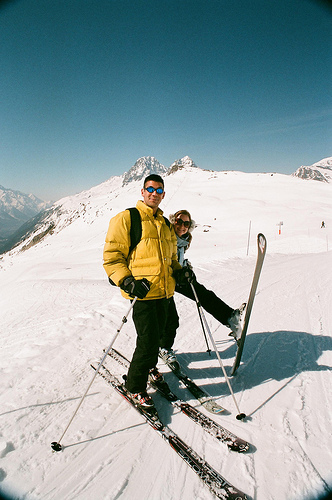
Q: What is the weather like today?
A: It is clear.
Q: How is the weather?
A: It is clear.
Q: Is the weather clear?
A: Yes, it is clear.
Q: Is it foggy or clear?
A: It is clear.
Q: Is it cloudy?
A: No, it is clear.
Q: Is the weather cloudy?
A: No, it is clear.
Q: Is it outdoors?
A: Yes, it is outdoors.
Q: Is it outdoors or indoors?
A: It is outdoors.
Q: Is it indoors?
A: No, it is outdoors.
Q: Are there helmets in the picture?
A: No, there are no helmets.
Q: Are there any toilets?
A: No, there are no toilets.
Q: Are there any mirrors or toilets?
A: No, there are no toilets or mirrors.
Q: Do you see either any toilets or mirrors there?
A: No, there are no toilets or mirrors.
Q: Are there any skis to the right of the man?
A: Yes, there is a ski to the right of the man.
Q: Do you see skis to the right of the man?
A: Yes, there is a ski to the right of the man.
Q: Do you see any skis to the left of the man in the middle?
A: No, the ski is to the right of the man.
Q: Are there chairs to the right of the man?
A: No, there is a ski to the right of the man.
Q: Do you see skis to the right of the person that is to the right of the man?
A: Yes, there is a ski to the right of the person.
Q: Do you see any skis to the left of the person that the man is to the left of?
A: No, the ski is to the right of the person.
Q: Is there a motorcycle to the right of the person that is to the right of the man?
A: No, there is a ski to the right of the person.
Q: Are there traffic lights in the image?
A: No, there are no traffic lights.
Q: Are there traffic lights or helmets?
A: No, there are no traffic lights or helmets.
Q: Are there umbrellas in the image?
A: No, there are no umbrellas.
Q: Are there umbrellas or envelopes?
A: No, there are no umbrellas or envelopes.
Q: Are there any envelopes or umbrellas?
A: No, there are no umbrellas or envelopes.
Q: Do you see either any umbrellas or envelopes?
A: No, there are no umbrellas or envelopes.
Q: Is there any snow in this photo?
A: Yes, there is snow.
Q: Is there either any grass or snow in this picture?
A: Yes, there is snow.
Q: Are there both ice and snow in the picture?
A: No, there is snow but no ice.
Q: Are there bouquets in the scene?
A: No, there are no bouquets.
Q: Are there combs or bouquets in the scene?
A: No, there are no bouquets or combs.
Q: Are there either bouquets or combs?
A: No, there are no bouquets or combs.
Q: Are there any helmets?
A: No, there are no helmets.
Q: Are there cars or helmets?
A: No, there are no helmets or cars.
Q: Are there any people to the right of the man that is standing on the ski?
A: Yes, there is a person to the right of the man.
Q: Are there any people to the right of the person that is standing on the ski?
A: Yes, there is a person to the right of the man.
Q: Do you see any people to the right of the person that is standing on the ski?
A: Yes, there is a person to the right of the man.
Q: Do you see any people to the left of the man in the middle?
A: No, the person is to the right of the man.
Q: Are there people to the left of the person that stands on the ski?
A: No, the person is to the right of the man.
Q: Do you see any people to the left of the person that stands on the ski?
A: No, the person is to the right of the man.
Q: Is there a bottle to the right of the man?
A: No, there is a person to the right of the man.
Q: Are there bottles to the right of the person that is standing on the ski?
A: No, there is a person to the right of the man.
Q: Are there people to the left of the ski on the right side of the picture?
A: Yes, there is a person to the left of the ski.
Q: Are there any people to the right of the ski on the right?
A: No, the person is to the left of the ski.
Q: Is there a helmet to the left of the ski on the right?
A: No, there is a person to the left of the ski.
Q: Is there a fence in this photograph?
A: No, there are no fences.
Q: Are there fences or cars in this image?
A: No, there are no fences or cars.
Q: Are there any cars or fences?
A: No, there are no fences or cars.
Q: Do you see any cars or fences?
A: No, there are no fences or cars.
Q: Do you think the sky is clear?
A: Yes, the sky is clear.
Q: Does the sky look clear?
A: Yes, the sky is clear.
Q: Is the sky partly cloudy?
A: No, the sky is clear.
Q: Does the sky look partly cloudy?
A: No, the sky is clear.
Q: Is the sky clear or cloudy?
A: The sky is clear.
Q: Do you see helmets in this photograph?
A: No, there are no helmets.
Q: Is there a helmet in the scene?
A: No, there are no helmets.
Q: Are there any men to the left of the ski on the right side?
A: Yes, there is a man to the left of the ski.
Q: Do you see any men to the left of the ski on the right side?
A: Yes, there is a man to the left of the ski.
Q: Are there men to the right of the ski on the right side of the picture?
A: No, the man is to the left of the ski.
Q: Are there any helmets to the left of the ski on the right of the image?
A: No, there is a man to the left of the ski.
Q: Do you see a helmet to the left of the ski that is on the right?
A: No, there is a man to the left of the ski.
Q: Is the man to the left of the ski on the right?
A: Yes, the man is to the left of the ski.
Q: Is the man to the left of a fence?
A: No, the man is to the left of the ski.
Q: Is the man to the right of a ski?
A: No, the man is to the left of a ski.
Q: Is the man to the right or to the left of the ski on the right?
A: The man is to the left of the ski.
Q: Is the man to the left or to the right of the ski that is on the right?
A: The man is to the left of the ski.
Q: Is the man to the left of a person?
A: Yes, the man is to the left of a person.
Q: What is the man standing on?
A: The man is standing on the ski.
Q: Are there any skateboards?
A: No, there are no skateboards.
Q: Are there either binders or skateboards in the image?
A: No, there are no skateboards or binders.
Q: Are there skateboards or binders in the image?
A: No, there are no skateboards or binders.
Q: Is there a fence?
A: No, there are no fences.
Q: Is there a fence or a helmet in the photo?
A: No, there are no fences or helmets.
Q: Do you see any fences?
A: No, there are no fences.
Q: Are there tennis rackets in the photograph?
A: No, there are no tennis rackets.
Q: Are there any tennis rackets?
A: No, there are no tennis rackets.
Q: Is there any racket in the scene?
A: No, there are no rackets.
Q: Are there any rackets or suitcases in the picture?
A: No, there are no rackets or suitcases.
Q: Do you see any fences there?
A: No, there are no fences.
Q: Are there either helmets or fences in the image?
A: No, there are no fences or helmets.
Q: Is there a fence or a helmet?
A: No, there are no fences or helmets.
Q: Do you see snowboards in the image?
A: No, there are no snowboards.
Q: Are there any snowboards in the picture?
A: No, there are no snowboards.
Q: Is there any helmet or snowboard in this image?
A: No, there are no snowboards or helmets.